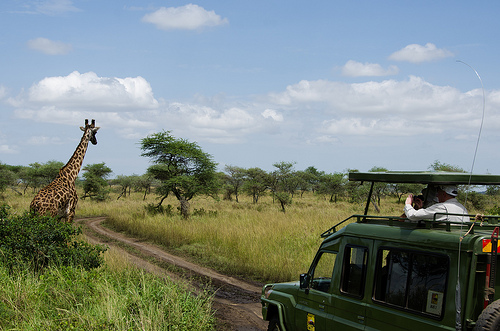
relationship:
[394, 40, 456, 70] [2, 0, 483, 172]
clouds in sky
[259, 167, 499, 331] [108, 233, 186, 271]
vehicle coming down road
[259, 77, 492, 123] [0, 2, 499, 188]
clouds in sky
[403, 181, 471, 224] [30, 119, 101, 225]
man watching adult giraffe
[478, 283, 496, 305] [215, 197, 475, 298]
tire on back of truck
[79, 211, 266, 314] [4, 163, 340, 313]
pathway through wilderness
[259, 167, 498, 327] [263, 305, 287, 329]
vehicle has tire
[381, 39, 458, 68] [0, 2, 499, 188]
cloud in sky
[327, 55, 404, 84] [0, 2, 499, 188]
cloud in sky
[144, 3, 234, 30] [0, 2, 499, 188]
cloud in sky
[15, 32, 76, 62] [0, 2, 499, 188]
cloud in sky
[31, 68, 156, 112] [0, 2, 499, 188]
cloud in sky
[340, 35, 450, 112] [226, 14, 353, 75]
white clouds in blue sky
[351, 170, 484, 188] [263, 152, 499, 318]
canopy on top of truck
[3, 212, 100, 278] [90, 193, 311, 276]
bushes on plain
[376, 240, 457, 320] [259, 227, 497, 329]
windows on truck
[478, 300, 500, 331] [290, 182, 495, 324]
tire on back of truck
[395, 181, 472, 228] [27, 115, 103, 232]
guy looking at giraffe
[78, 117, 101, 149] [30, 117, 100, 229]
head of adult giraffe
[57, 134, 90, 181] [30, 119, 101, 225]
neck on adult giraffe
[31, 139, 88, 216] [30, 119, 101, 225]
spots on adult giraffe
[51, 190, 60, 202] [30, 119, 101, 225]
spot on adult giraffe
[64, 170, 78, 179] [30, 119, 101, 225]
spot on adult giraffe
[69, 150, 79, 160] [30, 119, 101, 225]
spot on adult giraffe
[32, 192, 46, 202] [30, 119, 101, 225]
spot on adult giraffe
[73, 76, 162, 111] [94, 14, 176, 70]
clouds in sky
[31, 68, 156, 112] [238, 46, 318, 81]
cloud in sky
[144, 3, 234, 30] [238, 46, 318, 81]
cloud in sky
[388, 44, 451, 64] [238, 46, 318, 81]
cloud in sky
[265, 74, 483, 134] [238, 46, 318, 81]
cloud in sky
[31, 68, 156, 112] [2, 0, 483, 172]
cloud in sky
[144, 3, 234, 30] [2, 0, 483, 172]
cloud in sky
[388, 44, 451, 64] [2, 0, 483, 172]
cloud in sky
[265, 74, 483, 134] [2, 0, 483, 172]
cloud in sky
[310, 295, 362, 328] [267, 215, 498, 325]
doors on truck